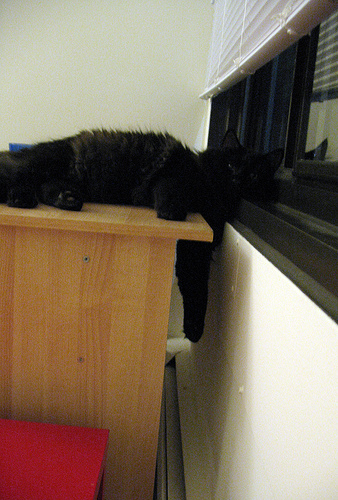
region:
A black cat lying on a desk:
[6, 122, 275, 346]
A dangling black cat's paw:
[175, 240, 217, 345]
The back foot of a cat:
[50, 185, 88, 213]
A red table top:
[2, 414, 114, 498]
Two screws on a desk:
[74, 250, 93, 365]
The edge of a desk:
[5, 212, 216, 245]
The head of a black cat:
[201, 124, 291, 215]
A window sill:
[228, 194, 337, 324]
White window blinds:
[195, 2, 336, 103]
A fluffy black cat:
[1, 120, 283, 347]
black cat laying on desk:
[12, 113, 270, 216]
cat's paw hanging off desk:
[178, 237, 203, 342]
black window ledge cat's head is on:
[207, 155, 337, 292]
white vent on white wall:
[164, 331, 196, 499]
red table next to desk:
[1, 416, 112, 499]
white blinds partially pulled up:
[204, 2, 336, 99]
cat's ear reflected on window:
[298, 138, 328, 161]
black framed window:
[208, 51, 330, 304]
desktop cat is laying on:
[0, 193, 219, 244]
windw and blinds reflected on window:
[285, 48, 336, 172]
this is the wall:
[83, 15, 170, 72]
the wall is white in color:
[34, 5, 107, 61]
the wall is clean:
[39, 13, 106, 63]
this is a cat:
[1, 127, 283, 221]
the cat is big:
[7, 132, 289, 220]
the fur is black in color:
[93, 146, 138, 166]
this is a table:
[2, 205, 163, 498]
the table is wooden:
[9, 248, 142, 368]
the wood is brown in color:
[72, 306, 118, 325]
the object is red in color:
[7, 425, 67, 497]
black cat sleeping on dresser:
[12, 126, 236, 214]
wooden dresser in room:
[19, 213, 256, 486]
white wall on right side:
[195, 258, 335, 472]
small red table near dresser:
[1, 425, 121, 491]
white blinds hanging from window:
[204, 5, 335, 84]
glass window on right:
[246, 54, 333, 161]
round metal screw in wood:
[80, 255, 95, 266]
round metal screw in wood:
[70, 353, 93, 366]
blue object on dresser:
[7, 136, 32, 154]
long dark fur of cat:
[91, 111, 165, 156]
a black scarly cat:
[8, 133, 259, 188]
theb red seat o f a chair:
[0, 420, 108, 498]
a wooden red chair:
[1, 423, 110, 498]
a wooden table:
[36, 230, 139, 295]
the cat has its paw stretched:
[174, 159, 227, 339]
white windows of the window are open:
[219, 3, 309, 81]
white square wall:
[211, 386, 298, 471]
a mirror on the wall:
[298, 91, 337, 161]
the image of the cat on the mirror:
[302, 131, 328, 159]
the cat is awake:
[191, 157, 275, 207]